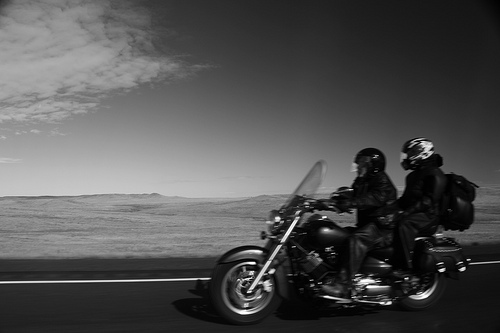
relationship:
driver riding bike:
[319, 148, 399, 299] [211, 160, 469, 325]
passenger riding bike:
[373, 135, 448, 278] [211, 160, 469, 325]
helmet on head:
[351, 142, 389, 178] [350, 143, 391, 178]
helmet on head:
[399, 133, 434, 170] [397, 133, 433, 172]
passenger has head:
[373, 135, 448, 278] [397, 133, 433, 172]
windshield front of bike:
[276, 159, 328, 217] [208, 158, 468, 325]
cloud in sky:
[4, 8, 201, 147] [6, 14, 499, 194]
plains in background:
[1, 183, 500, 260] [5, 5, 500, 257]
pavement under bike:
[3, 248, 499, 327] [208, 158, 468, 325]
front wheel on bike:
[209, 257, 283, 325] [208, 158, 468, 325]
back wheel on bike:
[400, 273, 448, 309] [208, 158, 468, 325]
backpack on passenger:
[437, 172, 485, 228] [373, 135, 448, 278]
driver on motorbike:
[319, 148, 399, 299] [316, 144, 403, 296]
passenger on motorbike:
[373, 135, 448, 278] [316, 144, 403, 296]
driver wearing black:
[319, 148, 399, 299] [323, 154, 483, 294]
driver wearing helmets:
[319, 148, 399, 299] [348, 138, 442, 174]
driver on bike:
[319, 148, 399, 299] [211, 160, 469, 325]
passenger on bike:
[373, 135, 448, 278] [211, 160, 469, 325]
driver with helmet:
[319, 148, 399, 299] [351, 142, 389, 178]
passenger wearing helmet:
[373, 135, 448, 278] [399, 133, 434, 170]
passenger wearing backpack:
[373, 135, 448, 278] [437, 172, 485, 228]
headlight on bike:
[263, 208, 282, 237] [211, 160, 469, 325]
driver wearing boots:
[319, 148, 399, 299] [318, 281, 349, 293]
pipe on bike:
[314, 290, 400, 312] [211, 160, 469, 325]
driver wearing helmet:
[319, 148, 399, 299] [351, 142, 389, 178]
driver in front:
[319, 148, 399, 299] [209, 153, 348, 317]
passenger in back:
[373, 135, 448, 278] [393, 135, 481, 301]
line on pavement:
[0, 256, 500, 285] [3, 248, 499, 327]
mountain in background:
[6, 191, 499, 256] [5, 5, 500, 257]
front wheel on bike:
[209, 257, 283, 320] [211, 160, 469, 325]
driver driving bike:
[319, 148, 399, 299] [211, 160, 469, 325]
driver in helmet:
[319, 148, 399, 299] [351, 142, 389, 178]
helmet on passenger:
[399, 133, 434, 170] [387, 129, 481, 286]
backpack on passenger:
[437, 172, 485, 228] [387, 129, 481, 286]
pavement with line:
[3, 248, 499, 327] [0, 256, 500, 287]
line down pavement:
[0, 256, 500, 287] [3, 248, 499, 327]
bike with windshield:
[211, 160, 469, 325] [276, 159, 328, 217]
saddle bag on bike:
[413, 237, 475, 273] [208, 158, 468, 325]